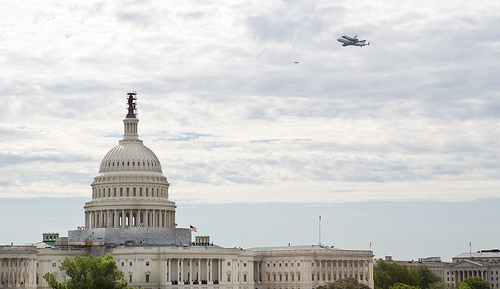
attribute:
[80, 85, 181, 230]
dome — large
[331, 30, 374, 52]
airplane — flying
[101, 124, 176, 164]
roof — large, white, dome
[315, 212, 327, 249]
pole — distant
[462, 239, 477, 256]
pole — distant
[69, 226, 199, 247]
partition — construction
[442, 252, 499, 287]
building — small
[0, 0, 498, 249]
sky — blue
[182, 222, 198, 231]
american flag — american 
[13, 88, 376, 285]
building — large, ornate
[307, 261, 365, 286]
pillars — white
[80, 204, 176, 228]
pillars — white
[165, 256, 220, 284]
pillars — white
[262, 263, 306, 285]
pillars — white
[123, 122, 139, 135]
pillars — white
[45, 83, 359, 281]
building — capital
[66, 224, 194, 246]
fence — white, construction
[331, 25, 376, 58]
plane — large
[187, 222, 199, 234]
flag — red